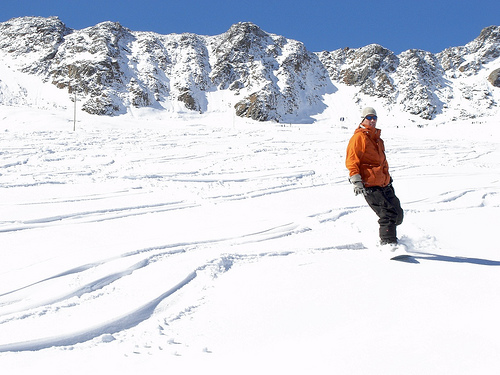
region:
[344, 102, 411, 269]
man using snow board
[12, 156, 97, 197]
white snow on hill side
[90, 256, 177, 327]
white snow on hill side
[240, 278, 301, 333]
white snow on hill side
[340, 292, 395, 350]
white snow on hill side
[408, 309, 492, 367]
white snow on hill side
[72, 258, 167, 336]
white snow on hill side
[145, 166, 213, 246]
white snow on hill side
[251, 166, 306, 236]
white snow on hill side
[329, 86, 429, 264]
snowboarder in the snow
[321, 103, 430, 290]
snowboarder in the snow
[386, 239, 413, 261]
a white snow board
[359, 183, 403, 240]
black ski pants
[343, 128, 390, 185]
a large orange snow jacket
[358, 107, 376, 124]
a white beanie on his head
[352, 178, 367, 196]
white snow gloves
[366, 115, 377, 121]
sunglasses on the man's face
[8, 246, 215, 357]
tracks in the snow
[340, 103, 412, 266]
a man on a snowboard on the slope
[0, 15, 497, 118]
snow covered mountains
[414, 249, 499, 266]
man's shadow on the snow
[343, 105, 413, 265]
a snowboarder on the slopes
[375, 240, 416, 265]
a white colored snowboard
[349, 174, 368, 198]
a grey ski glove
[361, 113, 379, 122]
adult male mirrored sunglasses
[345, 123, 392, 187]
an orange ski jacket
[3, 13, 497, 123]
a range of snowy mountains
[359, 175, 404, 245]
dark colored ski pants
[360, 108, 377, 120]
a white ski cap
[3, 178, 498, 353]
tracks created by skis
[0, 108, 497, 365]
a snowy ski slope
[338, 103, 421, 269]
a snowboarder going down a mountain.